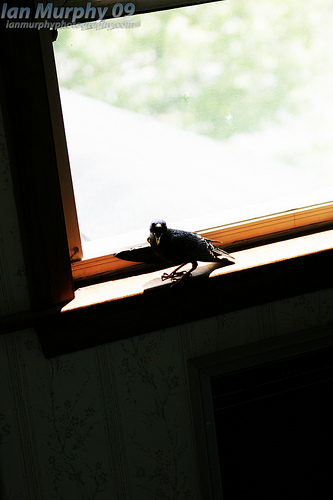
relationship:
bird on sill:
[145, 220, 236, 288] [1, 197, 332, 336]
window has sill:
[2, 1, 332, 359] [1, 197, 332, 336]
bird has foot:
[145, 220, 236, 288] [162, 270, 194, 281]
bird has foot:
[145, 220, 236, 288] [168, 270, 193, 289]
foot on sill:
[162, 270, 194, 281] [1, 197, 332, 336]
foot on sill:
[168, 270, 193, 289] [1, 197, 332, 336]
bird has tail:
[145, 220, 236, 288] [207, 239, 236, 266]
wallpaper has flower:
[0, 135, 331, 500] [116, 327, 181, 426]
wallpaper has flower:
[0, 135, 331, 500] [140, 432, 193, 499]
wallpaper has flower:
[0, 135, 331, 500] [33, 378, 100, 486]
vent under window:
[185, 320, 332, 500] [2, 1, 332, 359]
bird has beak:
[145, 220, 236, 288] [153, 234, 163, 245]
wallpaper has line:
[0, 135, 331, 500] [94, 340, 138, 500]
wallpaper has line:
[0, 135, 331, 500] [4, 328, 41, 499]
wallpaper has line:
[0, 135, 331, 500] [175, 319, 201, 362]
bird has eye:
[145, 220, 236, 288] [152, 230, 157, 238]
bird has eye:
[145, 220, 236, 288] [159, 231, 165, 236]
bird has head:
[145, 220, 236, 288] [149, 221, 167, 245]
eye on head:
[152, 230, 157, 238] [149, 221, 167, 245]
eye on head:
[159, 231, 165, 236] [149, 221, 167, 245]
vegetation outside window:
[52, 1, 332, 143] [2, 1, 332, 359]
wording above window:
[2, 1, 142, 30] [2, 1, 332, 359]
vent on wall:
[185, 320, 332, 500] [1, 0, 332, 499]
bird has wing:
[145, 220, 236, 288] [201, 237, 222, 245]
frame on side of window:
[1, 1, 76, 310] [2, 1, 332, 359]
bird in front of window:
[145, 220, 236, 288] [2, 1, 332, 359]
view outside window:
[53, 0, 332, 261] [2, 1, 332, 359]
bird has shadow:
[145, 220, 236, 288] [144, 261, 235, 286]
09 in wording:
[111, 1, 138, 18] [2, 1, 142, 30]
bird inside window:
[145, 220, 236, 288] [2, 1, 332, 359]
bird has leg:
[145, 220, 236, 288] [161, 259, 189, 282]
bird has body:
[145, 220, 236, 288] [148, 230, 217, 266]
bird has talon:
[145, 220, 236, 288] [162, 272, 171, 275]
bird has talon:
[145, 220, 236, 288] [160, 274, 169, 281]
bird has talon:
[145, 220, 236, 288] [170, 276, 180, 281]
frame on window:
[39, 27, 84, 263] [2, 1, 332, 359]